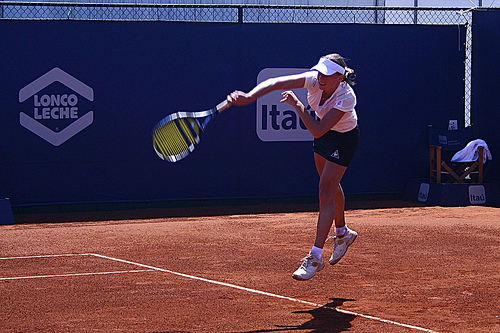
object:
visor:
[309, 56, 346, 76]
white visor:
[308, 56, 345, 76]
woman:
[231, 43, 388, 293]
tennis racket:
[149, 96, 232, 164]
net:
[177, 118, 196, 145]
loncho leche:
[31, 92, 81, 120]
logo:
[312, 78, 317, 88]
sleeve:
[332, 91, 357, 113]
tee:
[300, 70, 359, 134]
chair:
[405, 139, 493, 206]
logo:
[16, 65, 93, 145]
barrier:
[0, 17, 498, 227]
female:
[225, 51, 361, 282]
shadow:
[242, 297, 358, 332]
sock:
[305, 242, 325, 266]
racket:
[151, 89, 241, 163]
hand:
[226, 90, 248, 107]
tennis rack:
[150, 96, 232, 164]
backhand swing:
[151, 73, 305, 164]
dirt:
[115, 228, 158, 255]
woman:
[226, 53, 361, 281]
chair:
[430, 138, 483, 183]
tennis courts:
[0, 246, 443, 326]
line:
[0, 268, 140, 280]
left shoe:
[291, 253, 326, 281]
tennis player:
[150, 53, 361, 283]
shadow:
[246, 297, 357, 332]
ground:
[332, 270, 377, 292]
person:
[225, 52, 363, 282]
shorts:
[312, 123, 359, 168]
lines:
[50, 252, 196, 277]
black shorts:
[310, 115, 362, 169]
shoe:
[291, 252, 326, 281]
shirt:
[302, 70, 359, 133]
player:
[225, 53, 362, 283]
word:
[32, 93, 80, 119]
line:
[92, 252, 184, 278]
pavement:
[412, 204, 498, 230]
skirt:
[313, 123, 361, 167]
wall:
[15, 145, 143, 201]